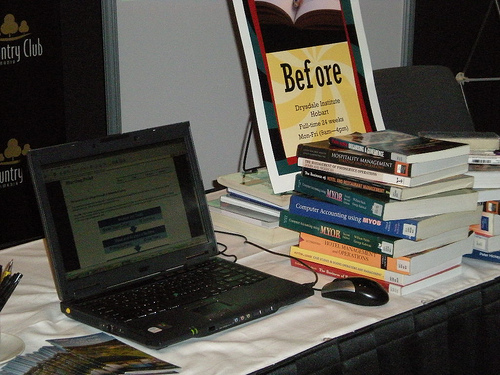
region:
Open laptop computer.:
[26, 118, 316, 353]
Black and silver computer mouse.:
[319, 275, 389, 305]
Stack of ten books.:
[278, 104, 484, 298]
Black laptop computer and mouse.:
[24, 112, 391, 347]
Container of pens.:
[0, 258, 24, 373]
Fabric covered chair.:
[372, 62, 477, 135]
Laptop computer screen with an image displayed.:
[37, 138, 210, 285]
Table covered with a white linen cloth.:
[0, 133, 499, 373]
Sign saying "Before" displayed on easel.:
[223, 0, 386, 197]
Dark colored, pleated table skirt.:
[243, 276, 498, 374]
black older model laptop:
[26, 145, 302, 360]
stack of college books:
[293, 139, 497, 309]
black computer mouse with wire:
[300, 263, 400, 325]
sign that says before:
[250, 14, 389, 192]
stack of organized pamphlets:
[23, 329, 150, 373]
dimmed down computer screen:
[49, 170, 213, 243]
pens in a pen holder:
[2, 257, 37, 338]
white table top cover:
[216, 323, 353, 355]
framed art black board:
[11, 3, 110, 216]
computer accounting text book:
[294, 197, 389, 232]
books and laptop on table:
[45, 40, 476, 346]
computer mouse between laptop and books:
[195, 210, 435, 316]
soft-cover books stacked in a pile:
[271, 120, 482, 300]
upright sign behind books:
[231, 15, 403, 195]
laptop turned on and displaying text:
[20, 106, 320, 354]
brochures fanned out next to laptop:
[10, 288, 276, 367]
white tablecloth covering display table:
[21, 190, 486, 352]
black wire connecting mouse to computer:
[205, 216, 355, 308]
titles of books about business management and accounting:
[271, 136, 418, 301]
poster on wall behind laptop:
[10, 10, 130, 265]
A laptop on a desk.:
[25, 110, 311, 340]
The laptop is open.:
[18, 127, 298, 341]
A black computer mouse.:
[314, 267, 395, 310]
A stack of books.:
[293, 109, 483, 276]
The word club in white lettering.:
[21, 33, 50, 61]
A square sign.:
[218, 8, 393, 135]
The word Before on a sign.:
[277, 54, 358, 94]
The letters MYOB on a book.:
[353, 211, 404, 234]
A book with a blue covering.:
[283, 205, 470, 237]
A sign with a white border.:
[231, 5, 385, 136]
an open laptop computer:
[20, 121, 314, 350]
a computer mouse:
[309, 274, 399, 309]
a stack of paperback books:
[283, 129, 476, 296]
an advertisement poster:
[228, 0, 383, 190]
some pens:
[0, 255, 21, 318]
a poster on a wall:
[2, 0, 112, 240]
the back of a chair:
[373, 62, 476, 133]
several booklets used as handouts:
[0, 325, 180, 371]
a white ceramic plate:
[0, 326, 25, 364]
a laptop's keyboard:
[80, 255, 275, 314]